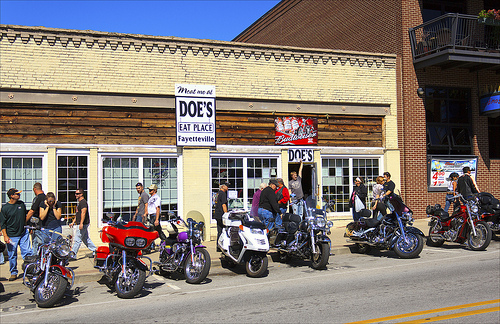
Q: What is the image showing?
A: It is showing a road.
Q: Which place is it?
A: It is a road.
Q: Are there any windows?
A: Yes, there are windows.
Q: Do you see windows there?
A: Yes, there are windows.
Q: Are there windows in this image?
A: Yes, there are windows.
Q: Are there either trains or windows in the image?
A: Yes, there are windows.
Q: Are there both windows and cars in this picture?
A: No, there are windows but no cars.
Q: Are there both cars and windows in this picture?
A: No, there are windows but no cars.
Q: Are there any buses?
A: No, there are no buses.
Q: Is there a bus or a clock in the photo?
A: No, there are no buses or clocks.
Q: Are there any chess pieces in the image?
A: No, there are no chess pieces.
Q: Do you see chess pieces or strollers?
A: No, there are no chess pieces or strollers.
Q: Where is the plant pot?
A: The plant pot is on the patio.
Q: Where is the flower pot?
A: The plant pot is on the patio.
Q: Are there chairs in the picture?
A: No, there are no chairs.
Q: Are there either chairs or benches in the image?
A: No, there are no chairs or benches.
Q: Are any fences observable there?
A: No, there are no fences.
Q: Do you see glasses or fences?
A: No, there are no fences or glasses.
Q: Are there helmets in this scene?
A: No, there are no helmets.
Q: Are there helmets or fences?
A: No, there are no helmets or fences.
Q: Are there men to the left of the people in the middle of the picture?
A: Yes, there is a man to the left of the people.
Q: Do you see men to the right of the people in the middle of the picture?
A: No, the man is to the left of the people.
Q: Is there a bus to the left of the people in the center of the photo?
A: No, there is a man to the left of the people.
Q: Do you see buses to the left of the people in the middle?
A: No, there is a man to the left of the people.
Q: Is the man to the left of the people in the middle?
A: Yes, the man is to the left of the people.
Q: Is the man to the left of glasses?
A: No, the man is to the left of the people.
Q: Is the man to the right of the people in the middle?
A: No, the man is to the left of the people.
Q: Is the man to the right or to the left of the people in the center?
A: The man is to the left of the people.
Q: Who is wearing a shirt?
A: The man is wearing a shirt.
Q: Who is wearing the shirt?
A: The man is wearing a shirt.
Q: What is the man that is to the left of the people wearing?
A: The man is wearing a shirt.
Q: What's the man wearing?
A: The man is wearing a shirt.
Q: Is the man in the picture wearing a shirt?
A: Yes, the man is wearing a shirt.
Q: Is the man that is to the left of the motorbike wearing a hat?
A: No, the man is wearing a shirt.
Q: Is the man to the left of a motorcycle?
A: Yes, the man is to the left of a motorcycle.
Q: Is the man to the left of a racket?
A: No, the man is to the left of a motorcycle.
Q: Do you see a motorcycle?
A: Yes, there is a motorcycle.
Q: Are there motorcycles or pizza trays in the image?
A: Yes, there is a motorcycle.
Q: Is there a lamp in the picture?
A: No, there are no lamps.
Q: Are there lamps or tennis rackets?
A: No, there are no lamps or tennis rackets.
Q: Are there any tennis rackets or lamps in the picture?
A: No, there are no lamps or tennis rackets.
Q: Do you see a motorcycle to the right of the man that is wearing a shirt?
A: Yes, there is a motorcycle to the right of the man.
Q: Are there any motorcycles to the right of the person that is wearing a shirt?
A: Yes, there is a motorcycle to the right of the man.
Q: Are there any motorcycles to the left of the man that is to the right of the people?
A: No, the motorcycle is to the right of the man.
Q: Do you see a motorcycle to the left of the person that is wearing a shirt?
A: No, the motorcycle is to the right of the man.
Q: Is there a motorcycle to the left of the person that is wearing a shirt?
A: No, the motorcycle is to the right of the man.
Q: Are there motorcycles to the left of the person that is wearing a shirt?
A: No, the motorcycle is to the right of the man.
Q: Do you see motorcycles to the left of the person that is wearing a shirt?
A: No, the motorcycle is to the right of the man.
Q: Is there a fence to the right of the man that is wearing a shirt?
A: No, there is a motorcycle to the right of the man.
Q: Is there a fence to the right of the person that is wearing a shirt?
A: No, there is a motorcycle to the right of the man.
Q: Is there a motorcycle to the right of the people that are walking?
A: Yes, there is a motorcycle to the right of the people.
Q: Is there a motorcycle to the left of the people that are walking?
A: No, the motorcycle is to the right of the people.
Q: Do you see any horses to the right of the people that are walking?
A: No, there is a motorcycle to the right of the people.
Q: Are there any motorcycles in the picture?
A: Yes, there is a motorcycle.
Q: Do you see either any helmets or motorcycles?
A: Yes, there is a motorcycle.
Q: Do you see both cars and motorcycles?
A: No, there is a motorcycle but no cars.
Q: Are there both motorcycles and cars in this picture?
A: No, there is a motorcycle but no cars.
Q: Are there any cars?
A: No, there are no cars.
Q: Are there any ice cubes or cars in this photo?
A: No, there are no cars or ice cubes.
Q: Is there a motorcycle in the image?
A: Yes, there is a motorcycle.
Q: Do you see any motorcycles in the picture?
A: Yes, there is a motorcycle.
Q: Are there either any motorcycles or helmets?
A: Yes, there is a motorcycle.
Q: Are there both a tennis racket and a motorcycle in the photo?
A: No, there is a motorcycle but no rackets.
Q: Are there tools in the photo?
A: No, there are no tools.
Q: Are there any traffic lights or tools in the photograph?
A: No, there are no tools or traffic lights.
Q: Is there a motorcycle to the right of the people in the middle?
A: Yes, there is a motorcycle to the right of the people.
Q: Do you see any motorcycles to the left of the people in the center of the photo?
A: No, the motorcycle is to the right of the people.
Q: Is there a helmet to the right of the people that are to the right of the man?
A: No, there is a motorcycle to the right of the people.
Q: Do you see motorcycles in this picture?
A: Yes, there is a motorcycle.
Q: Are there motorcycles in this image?
A: Yes, there is a motorcycle.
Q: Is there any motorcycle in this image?
A: Yes, there is a motorcycle.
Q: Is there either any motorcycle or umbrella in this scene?
A: Yes, there is a motorcycle.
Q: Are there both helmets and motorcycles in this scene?
A: No, there is a motorcycle but no helmets.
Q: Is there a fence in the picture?
A: No, there are no fences.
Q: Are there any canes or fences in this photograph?
A: No, there are no fences or canes.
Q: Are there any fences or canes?
A: No, there are no fences or canes.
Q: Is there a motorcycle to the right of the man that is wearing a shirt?
A: Yes, there is a motorcycle to the right of the man.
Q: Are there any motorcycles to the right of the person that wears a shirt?
A: Yes, there is a motorcycle to the right of the man.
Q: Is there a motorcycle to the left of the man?
A: No, the motorcycle is to the right of the man.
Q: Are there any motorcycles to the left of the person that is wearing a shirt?
A: No, the motorcycle is to the right of the man.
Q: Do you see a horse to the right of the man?
A: No, there is a motorcycle to the right of the man.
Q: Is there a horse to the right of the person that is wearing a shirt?
A: No, there is a motorcycle to the right of the man.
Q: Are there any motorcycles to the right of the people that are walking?
A: Yes, there is a motorcycle to the right of the people.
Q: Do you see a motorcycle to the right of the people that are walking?
A: Yes, there is a motorcycle to the right of the people.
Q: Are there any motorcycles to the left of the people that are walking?
A: No, the motorcycle is to the right of the people.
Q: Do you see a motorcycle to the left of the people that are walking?
A: No, the motorcycle is to the right of the people.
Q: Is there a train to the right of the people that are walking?
A: No, there is a motorcycle to the right of the people.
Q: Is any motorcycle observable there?
A: Yes, there is a motorcycle.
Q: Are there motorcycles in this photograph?
A: Yes, there is a motorcycle.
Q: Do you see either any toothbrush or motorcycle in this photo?
A: Yes, there is a motorcycle.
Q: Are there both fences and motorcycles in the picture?
A: No, there is a motorcycle but no fences.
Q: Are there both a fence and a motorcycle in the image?
A: No, there is a motorcycle but no fences.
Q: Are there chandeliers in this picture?
A: No, there are no chandeliers.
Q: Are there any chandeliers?
A: No, there are no chandeliers.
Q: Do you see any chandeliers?
A: No, there are no chandeliers.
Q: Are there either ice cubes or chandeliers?
A: No, there are no chandeliers or ice cubes.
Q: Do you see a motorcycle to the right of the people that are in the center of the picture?
A: Yes, there is a motorcycle to the right of the people.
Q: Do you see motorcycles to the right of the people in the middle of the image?
A: Yes, there is a motorcycle to the right of the people.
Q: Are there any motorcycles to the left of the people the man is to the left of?
A: No, the motorcycle is to the right of the people.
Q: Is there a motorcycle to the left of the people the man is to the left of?
A: No, the motorcycle is to the right of the people.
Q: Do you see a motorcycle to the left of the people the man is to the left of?
A: No, the motorcycle is to the right of the people.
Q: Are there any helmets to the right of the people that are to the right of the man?
A: No, there is a motorcycle to the right of the people.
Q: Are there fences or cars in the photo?
A: No, there are no cars or fences.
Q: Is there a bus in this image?
A: No, there are no buses.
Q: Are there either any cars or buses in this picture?
A: No, there are no buses or cars.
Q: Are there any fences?
A: No, there are no fences.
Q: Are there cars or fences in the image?
A: No, there are no fences or cars.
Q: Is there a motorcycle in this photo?
A: Yes, there is a motorcycle.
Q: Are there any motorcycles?
A: Yes, there is a motorcycle.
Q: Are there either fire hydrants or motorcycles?
A: Yes, there is a motorcycle.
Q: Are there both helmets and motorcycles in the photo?
A: No, there is a motorcycle but no helmets.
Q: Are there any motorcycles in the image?
A: Yes, there is a motorcycle.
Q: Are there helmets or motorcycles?
A: Yes, there is a motorcycle.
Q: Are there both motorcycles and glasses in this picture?
A: No, there is a motorcycle but no glasses.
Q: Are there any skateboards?
A: No, there are no skateboards.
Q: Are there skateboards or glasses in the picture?
A: No, there are no skateboards or glasses.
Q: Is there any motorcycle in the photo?
A: Yes, there are motorcycles.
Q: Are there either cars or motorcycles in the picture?
A: Yes, there are motorcycles.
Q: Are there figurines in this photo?
A: No, there are no figurines.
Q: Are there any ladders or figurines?
A: No, there are no figurines or ladders.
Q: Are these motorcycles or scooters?
A: These are motorcycles.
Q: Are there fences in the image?
A: No, there are no fences.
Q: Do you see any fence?
A: No, there are no fences.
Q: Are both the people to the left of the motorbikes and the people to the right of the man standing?
A: Yes, both the people and the people are standing.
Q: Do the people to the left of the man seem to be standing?
A: Yes, the people are standing.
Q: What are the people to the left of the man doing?
A: The people are standing.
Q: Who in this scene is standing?
A: The people are standing.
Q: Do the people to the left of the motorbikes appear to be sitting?
A: No, the people are standing.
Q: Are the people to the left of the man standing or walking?
A: The people are standing.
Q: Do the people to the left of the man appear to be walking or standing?
A: The people are standing.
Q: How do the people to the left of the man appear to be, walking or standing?
A: The people are standing.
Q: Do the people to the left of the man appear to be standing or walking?
A: The people are standing.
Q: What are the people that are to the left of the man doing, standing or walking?
A: The people are standing.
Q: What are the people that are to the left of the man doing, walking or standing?
A: The people are standing.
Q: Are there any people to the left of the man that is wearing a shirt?
A: Yes, there are people to the left of the man.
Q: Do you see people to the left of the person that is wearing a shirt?
A: Yes, there are people to the left of the man.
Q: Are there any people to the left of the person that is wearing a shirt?
A: Yes, there are people to the left of the man.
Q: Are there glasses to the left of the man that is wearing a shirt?
A: No, there are people to the left of the man.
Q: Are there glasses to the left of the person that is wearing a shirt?
A: No, there are people to the left of the man.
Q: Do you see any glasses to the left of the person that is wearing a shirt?
A: No, there are people to the left of the man.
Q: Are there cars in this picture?
A: No, there are no cars.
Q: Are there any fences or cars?
A: No, there are no cars or fences.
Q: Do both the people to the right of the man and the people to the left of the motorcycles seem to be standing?
A: Yes, both the people and the people are standing.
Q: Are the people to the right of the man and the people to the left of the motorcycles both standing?
A: Yes, both the people and the people are standing.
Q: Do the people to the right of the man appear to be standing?
A: Yes, the people are standing.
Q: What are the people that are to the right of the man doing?
A: The people are standing.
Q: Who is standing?
A: The people are standing.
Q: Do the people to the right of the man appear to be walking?
A: No, the people are standing.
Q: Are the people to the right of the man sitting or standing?
A: The people are standing.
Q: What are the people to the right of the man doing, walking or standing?
A: The people are standing.